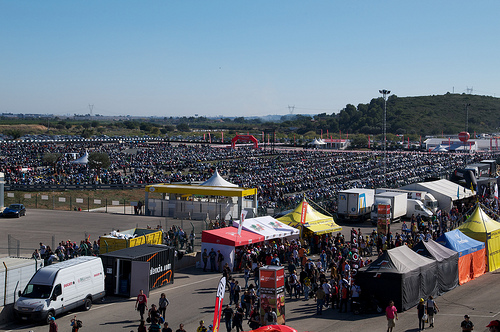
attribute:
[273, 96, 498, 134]
hill — green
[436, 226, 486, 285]
tent — orange, blue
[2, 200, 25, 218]
car — black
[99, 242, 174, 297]
storage container — black 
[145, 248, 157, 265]
stripe — orange 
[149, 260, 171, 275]
letters — white 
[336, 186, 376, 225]
truck — white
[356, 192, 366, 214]
design — blue, yellow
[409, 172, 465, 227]
tent — pop up, white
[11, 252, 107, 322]
van — white, commercial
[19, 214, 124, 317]
van — white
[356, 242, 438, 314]
tents — black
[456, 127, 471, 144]
balloon — red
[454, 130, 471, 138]
stripe — white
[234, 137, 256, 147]
arche — red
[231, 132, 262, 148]
arche — red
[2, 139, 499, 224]
lot — large 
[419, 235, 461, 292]
black tent — black 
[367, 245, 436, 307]
black tent — black 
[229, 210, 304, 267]
tent — white, pop up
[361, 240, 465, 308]
tent — yellow, red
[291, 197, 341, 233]
tent top — Long , yellow 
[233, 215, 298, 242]
white tent — white 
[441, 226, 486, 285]
tent — blue, orange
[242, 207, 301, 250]
white tent — white 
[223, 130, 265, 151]
arch — bright, red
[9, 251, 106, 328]
truck — white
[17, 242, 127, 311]
van — white 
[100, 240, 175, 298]
trailer — black , orange 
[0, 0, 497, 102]
sky — blue, hazy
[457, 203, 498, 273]
tent — pop up, yellow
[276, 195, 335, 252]
tent — pop up, yellow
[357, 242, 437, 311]
tent — pop up, yellow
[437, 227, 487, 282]
tent — pop up, yellow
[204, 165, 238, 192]
tent — pop up, white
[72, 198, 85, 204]
sign — white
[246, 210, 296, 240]
logos — red, green , white